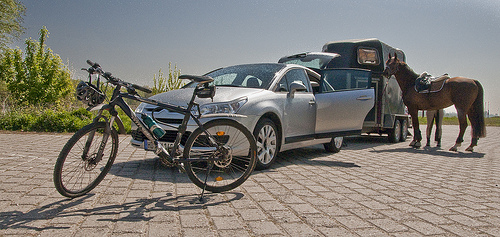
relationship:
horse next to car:
[380, 54, 488, 154] [129, 41, 346, 168]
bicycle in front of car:
[45, 48, 262, 199] [129, 41, 346, 168]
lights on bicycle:
[208, 124, 231, 193] [45, 48, 262, 199]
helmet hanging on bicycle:
[70, 59, 111, 107] [45, 48, 262, 199]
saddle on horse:
[415, 62, 451, 101] [380, 54, 488, 154]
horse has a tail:
[380, 54, 488, 154] [468, 78, 488, 143]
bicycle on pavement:
[45, 48, 262, 199] [3, 131, 496, 231]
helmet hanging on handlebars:
[70, 59, 111, 107] [80, 62, 158, 95]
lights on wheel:
[208, 124, 231, 193] [183, 113, 258, 195]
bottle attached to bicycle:
[136, 108, 170, 142] [45, 48, 262, 199]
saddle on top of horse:
[415, 62, 451, 101] [380, 54, 488, 154]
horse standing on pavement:
[380, 54, 488, 154] [3, 131, 496, 231]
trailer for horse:
[316, 31, 412, 149] [380, 54, 488, 154]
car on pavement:
[129, 41, 346, 168] [3, 131, 496, 231]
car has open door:
[129, 41, 346, 168] [311, 64, 376, 140]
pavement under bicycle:
[3, 131, 496, 231] [45, 48, 262, 199]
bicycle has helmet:
[45, 48, 262, 199] [70, 59, 111, 107]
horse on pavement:
[380, 54, 488, 154] [3, 131, 496, 231]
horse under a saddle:
[380, 54, 488, 154] [415, 62, 451, 101]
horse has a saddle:
[380, 54, 488, 154] [415, 62, 451, 101]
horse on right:
[380, 54, 488, 154] [375, 12, 498, 195]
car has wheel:
[129, 41, 346, 168] [247, 102, 286, 176]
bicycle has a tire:
[45, 48, 262, 199] [50, 120, 120, 199]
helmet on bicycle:
[70, 59, 111, 107] [45, 48, 262, 199]